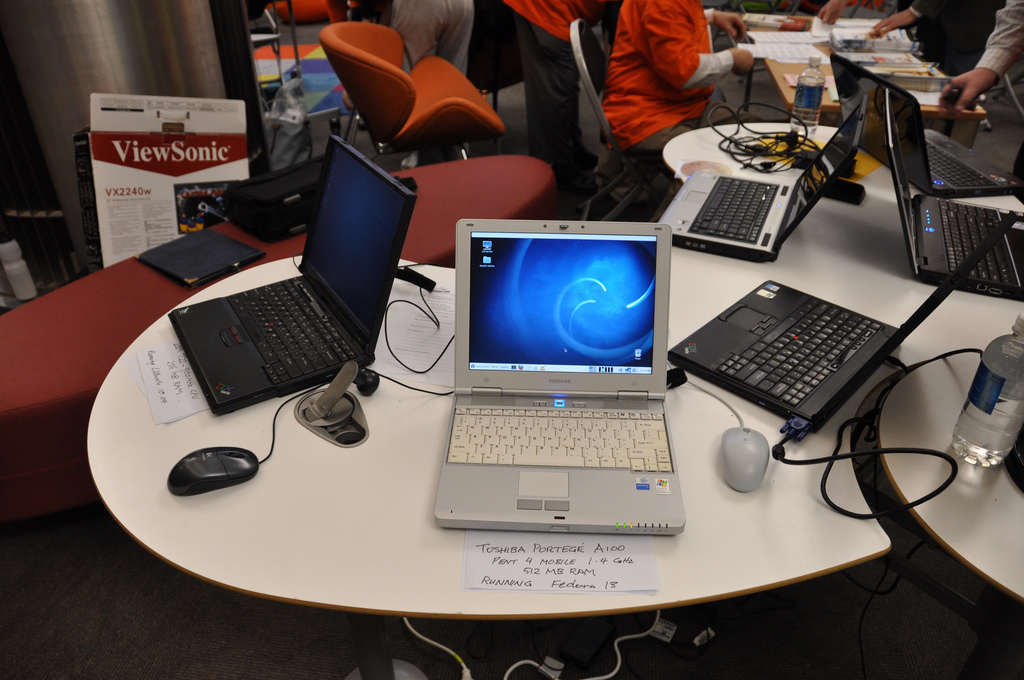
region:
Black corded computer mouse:
[160, 440, 275, 497]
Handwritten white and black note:
[469, 534, 678, 598]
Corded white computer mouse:
[716, 411, 778, 494]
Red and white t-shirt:
[611, 0, 730, 147]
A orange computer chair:
[306, 14, 513, 148]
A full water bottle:
[949, 310, 1022, 484]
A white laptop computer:
[432, 205, 692, 544]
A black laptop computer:
[166, 139, 420, 414]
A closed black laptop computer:
[137, 221, 265, 286]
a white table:
[87, 115, 1015, 635]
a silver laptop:
[433, 216, 683, 531]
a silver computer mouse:
[721, 418, 761, 502]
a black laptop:
[165, 133, 415, 413]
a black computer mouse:
[168, 443, 261, 495]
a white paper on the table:
[468, 522, 643, 598]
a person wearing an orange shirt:
[598, 16, 728, 140]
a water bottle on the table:
[792, 51, 811, 116]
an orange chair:
[313, 16, 497, 140]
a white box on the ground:
[87, 100, 247, 253]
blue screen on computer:
[482, 232, 651, 366]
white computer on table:
[441, 214, 685, 524]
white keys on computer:
[480, 393, 642, 476]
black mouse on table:
[142, 434, 286, 524]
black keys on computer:
[190, 292, 308, 388]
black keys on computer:
[739, 302, 864, 385]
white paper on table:
[460, 502, 686, 645]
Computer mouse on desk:
[701, 420, 777, 490]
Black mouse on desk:
[130, 440, 299, 494]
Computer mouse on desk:
[152, 440, 271, 492]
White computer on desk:
[441, 205, 718, 542]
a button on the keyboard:
[482, 437, 517, 463]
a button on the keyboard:
[476, 391, 514, 423]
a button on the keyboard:
[596, 423, 613, 434]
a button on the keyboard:
[617, 472, 625, 480]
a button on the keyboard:
[626, 385, 646, 428]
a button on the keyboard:
[552, 396, 569, 448]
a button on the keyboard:
[509, 423, 547, 443]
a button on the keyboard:
[500, 411, 535, 451]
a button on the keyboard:
[465, 411, 508, 475]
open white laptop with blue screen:
[425, 205, 691, 538]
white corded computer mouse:
[686, 376, 778, 498]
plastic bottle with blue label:
[949, 310, 1022, 466]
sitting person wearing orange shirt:
[570, 0, 757, 217]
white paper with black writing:
[459, 528, 663, 599]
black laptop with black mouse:
[162, 132, 413, 505]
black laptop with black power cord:
[671, 198, 1022, 515]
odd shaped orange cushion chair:
[314, 13, 499, 170]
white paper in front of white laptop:
[428, 208, 686, 597]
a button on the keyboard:
[580, 402, 626, 450]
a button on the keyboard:
[634, 414, 641, 450]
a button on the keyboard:
[587, 443, 616, 482]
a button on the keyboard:
[568, 381, 601, 451]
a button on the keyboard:
[554, 407, 580, 453]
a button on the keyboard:
[485, 351, 528, 443]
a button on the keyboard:
[543, 465, 553, 479]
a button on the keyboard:
[502, 402, 521, 475]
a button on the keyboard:
[590, 402, 633, 453]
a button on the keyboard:
[254, 341, 261, 355]